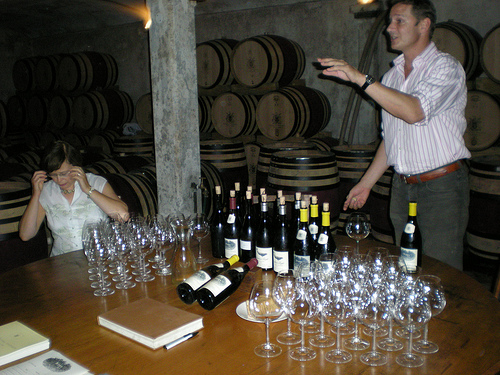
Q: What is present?
A: Glasses.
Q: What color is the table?
A: Brown.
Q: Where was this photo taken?
A: At a winery.